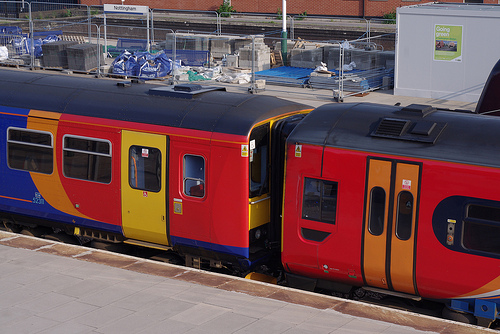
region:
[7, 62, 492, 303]
train cars on track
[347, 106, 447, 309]
double orange doors with windows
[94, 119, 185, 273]
yellow door with window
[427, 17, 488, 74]
green sign with white letters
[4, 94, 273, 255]
blue, orange, red, yellow train car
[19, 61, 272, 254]
black roof on train car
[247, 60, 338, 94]
blue-color materials on ground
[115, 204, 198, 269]
yellow step on train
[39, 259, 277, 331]
brick pavers on train platform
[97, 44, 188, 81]
blue bags by train tracks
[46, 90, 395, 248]
this is a train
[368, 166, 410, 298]
this is the door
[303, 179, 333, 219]
this is the window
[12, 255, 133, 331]
this is the ground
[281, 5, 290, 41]
this is a pole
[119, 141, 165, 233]
the door is yellow in color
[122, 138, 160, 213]
the door is closed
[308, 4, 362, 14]
this is a roof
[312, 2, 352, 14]
the roof is red in color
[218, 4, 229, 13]
this is tree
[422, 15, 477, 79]
blue and green poster on wall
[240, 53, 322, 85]
blue cover on building ground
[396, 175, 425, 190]
small white sign on train door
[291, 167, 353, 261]
large curved window on train side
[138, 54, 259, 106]
blue vent on top of train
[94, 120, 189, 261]
yellow door with black border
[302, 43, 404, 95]
large blue chain link fence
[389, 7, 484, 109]
large gray building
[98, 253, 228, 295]
brown tiles at edge of platform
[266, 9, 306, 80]
large green and white post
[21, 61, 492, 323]
the train is on the tracks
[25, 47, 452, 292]
the train is red, yellow and blue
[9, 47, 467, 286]
the train is stopped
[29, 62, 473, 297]
the train has people on it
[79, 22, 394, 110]
the supplies are waiting for delivery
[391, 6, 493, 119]
a building with a sign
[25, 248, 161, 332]
tan tile on the sidewalk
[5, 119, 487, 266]
several windows are on the train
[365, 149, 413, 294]
the door is orange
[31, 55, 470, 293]
the trains are connected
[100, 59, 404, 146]
Black top on train.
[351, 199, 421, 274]
Yellow door on train.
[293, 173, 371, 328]
Window on train.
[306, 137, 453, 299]
Train car is mostly red.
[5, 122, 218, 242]
Windows on the side of train car.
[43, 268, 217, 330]
Concrete area next to train.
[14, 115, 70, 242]
Orange section on train.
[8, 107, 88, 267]
Blue section on train.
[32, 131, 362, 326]
Train is on tracks.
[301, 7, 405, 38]
Brick building in background.